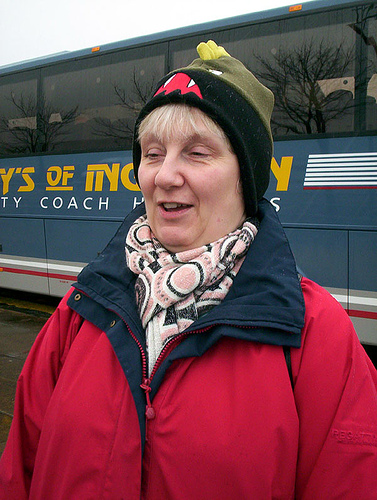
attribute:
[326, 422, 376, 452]
logo — one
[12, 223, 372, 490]
coat — one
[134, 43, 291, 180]
hat — funny, winter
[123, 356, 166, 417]
zipper — red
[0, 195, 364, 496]
jacket — red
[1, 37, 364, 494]
woman — older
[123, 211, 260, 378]
scarf — colorful, multicolored, pink, black, and white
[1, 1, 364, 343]
bus — huge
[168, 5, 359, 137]
window — large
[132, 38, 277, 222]
hat — green and black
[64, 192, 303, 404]
lapel — blue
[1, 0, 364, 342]
passenger bus — large, blue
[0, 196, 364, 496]
coat — red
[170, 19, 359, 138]
window — tinted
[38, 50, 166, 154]
window — tinted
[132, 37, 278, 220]
cap — gray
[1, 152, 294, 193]
letters — yellow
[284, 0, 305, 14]
light — orange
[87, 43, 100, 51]
light — orange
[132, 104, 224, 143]
hair — white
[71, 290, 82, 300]
button — brown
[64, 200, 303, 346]
collar — blue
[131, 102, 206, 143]
hair — short, blonde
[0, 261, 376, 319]
stripe — red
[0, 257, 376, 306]
stripe — white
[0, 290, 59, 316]
line — yellow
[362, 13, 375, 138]
window — tinted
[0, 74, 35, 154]
window — tinted